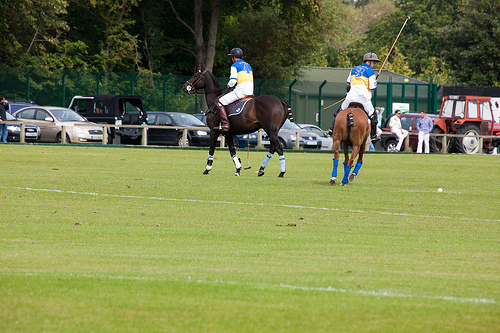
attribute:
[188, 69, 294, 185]
horse — brown, white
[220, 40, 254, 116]
rider — playing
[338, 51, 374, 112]
man — playing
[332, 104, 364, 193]
horse — brown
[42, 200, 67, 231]
grass — green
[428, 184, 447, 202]
ball — white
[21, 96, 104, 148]
car — silver